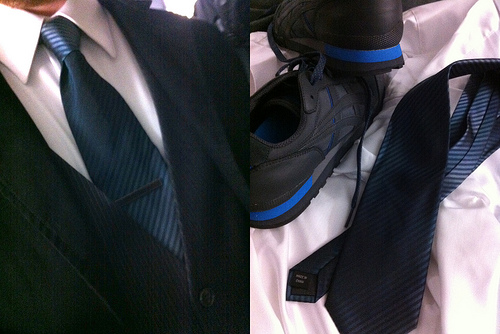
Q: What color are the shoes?
A: Black and blue.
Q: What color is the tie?
A: Black and navy blue.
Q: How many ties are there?
A: Two.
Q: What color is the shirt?
A: White.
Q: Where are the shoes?
A: On the shirt.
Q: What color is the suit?
A: Black.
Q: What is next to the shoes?
A: The tie.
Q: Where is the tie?
A: Above the shirt.